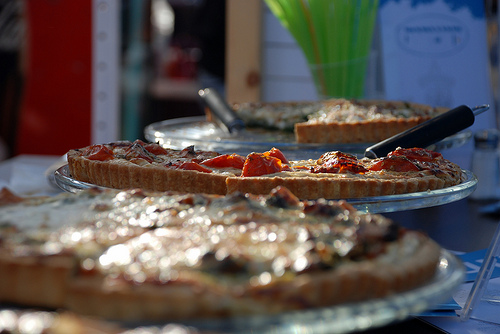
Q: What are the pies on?
A: Plates.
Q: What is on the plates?
A: Pies.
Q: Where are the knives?
A: On the pies.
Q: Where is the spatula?
A: On the plate.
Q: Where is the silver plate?
A: On the table.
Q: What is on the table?
A: Pies.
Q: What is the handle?
A: A spatula.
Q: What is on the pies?
A: Fruit.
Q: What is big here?
A: Plate.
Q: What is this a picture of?
A: Food.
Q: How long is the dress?
A: No dress.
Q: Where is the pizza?
A: On table.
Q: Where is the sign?
A: No sign.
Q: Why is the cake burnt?
A: No cake.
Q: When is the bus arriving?
A: No bus.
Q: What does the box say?
A: No box.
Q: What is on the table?
A: Three pies.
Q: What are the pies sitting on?
A: Glass plates.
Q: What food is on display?
A: Pizza.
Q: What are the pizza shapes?
A: Round.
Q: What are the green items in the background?
A: Straws.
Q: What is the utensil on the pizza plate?
A: Spatula.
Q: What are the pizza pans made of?
A: Metal.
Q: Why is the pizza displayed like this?
A: To be served.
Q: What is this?
A: Food.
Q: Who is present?
A: No one.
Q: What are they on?
A: Plates.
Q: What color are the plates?
A: Silver.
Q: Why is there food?
A: For eating.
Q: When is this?
A: Daytime.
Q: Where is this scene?
A: A dining room.